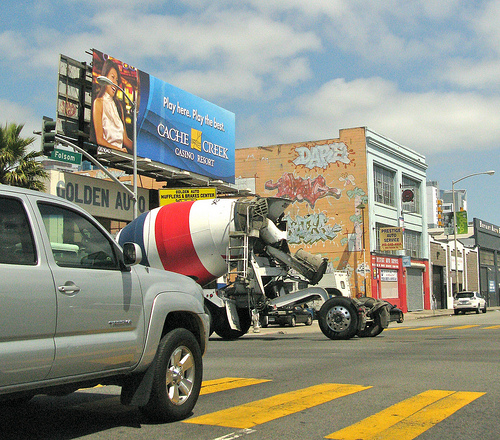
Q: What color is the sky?
A: Blue.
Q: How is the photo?
A: Clear.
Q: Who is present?
A: Nobody.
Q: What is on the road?
A: Yellow lines.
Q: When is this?
A: Daytime.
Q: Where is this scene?
A: In a city.